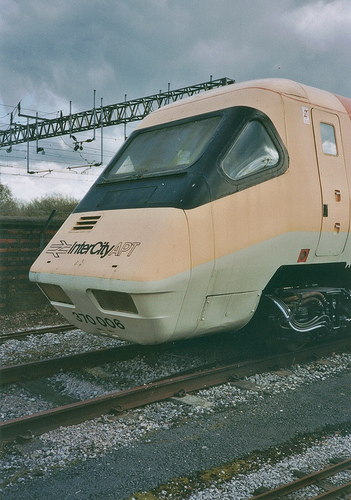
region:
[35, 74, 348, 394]
This is a train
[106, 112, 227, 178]
the windshield on the front of the train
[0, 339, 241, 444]
the railroad tracks on the ground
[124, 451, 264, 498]
the moss by the white rocks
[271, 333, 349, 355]
the wheels on the tracks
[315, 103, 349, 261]
the door on the train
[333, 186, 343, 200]
the handle on the door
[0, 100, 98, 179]
the wires above the train tracks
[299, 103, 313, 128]
the stickers on the side of the train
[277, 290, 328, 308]
the tubes under the train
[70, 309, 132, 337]
the numbers under the front of the train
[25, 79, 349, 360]
white train on tracks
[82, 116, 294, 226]
front window of train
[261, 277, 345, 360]
wheels of train on tracks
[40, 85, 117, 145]
metal wire bridge with wires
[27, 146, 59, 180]
several power wires in sky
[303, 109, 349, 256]
side white door on train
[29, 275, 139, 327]
two front headlights on train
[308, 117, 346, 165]
side window of train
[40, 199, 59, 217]
several green leafs of trees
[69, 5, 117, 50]
dark clouds in sky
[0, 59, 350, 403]
this is a train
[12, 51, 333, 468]
train on the tracks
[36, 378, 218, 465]
gravel on the ground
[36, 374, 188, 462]
gravel is light grey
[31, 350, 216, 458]
rusted brown train track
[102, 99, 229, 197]
front window of train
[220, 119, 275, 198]
side window of train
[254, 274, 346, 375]
electric part of train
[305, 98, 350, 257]
side door on train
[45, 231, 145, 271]
black writing on train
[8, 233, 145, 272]
logo on the train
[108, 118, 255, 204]
windshield of the train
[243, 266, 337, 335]
wheel on the train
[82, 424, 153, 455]
stones on the ground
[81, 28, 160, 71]
large clouds in sky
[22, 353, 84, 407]
metal on the tracks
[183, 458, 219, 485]
grass on the ground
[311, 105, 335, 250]
door on the train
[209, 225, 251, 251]
the train is tan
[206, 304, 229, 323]
the train is white